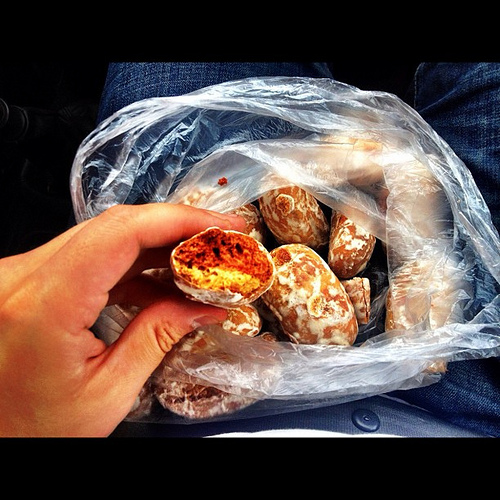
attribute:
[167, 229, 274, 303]
snacks — stuffed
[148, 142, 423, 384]
food — brown and white, small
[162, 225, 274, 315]
snack — bite size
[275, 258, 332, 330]
food — small, brown and white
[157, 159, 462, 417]
food — small, brown and white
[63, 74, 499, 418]
bag — clear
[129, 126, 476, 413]
bag — clear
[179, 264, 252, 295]
ingredients — yellow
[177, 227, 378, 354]
food — small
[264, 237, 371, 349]
food — white, brown, small